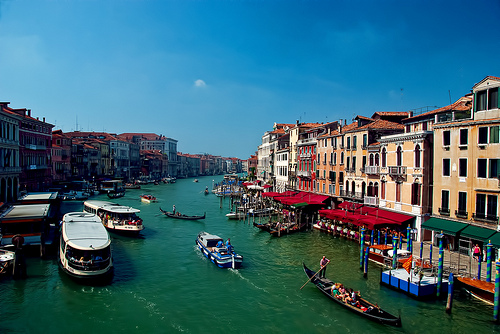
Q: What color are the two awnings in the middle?
A: Red.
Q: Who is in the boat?
A: Passengers.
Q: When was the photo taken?
A: Daytime.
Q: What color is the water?
A: Green.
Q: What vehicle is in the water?
A: Boat.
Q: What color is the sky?
A: Blue.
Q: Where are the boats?
A: Water.